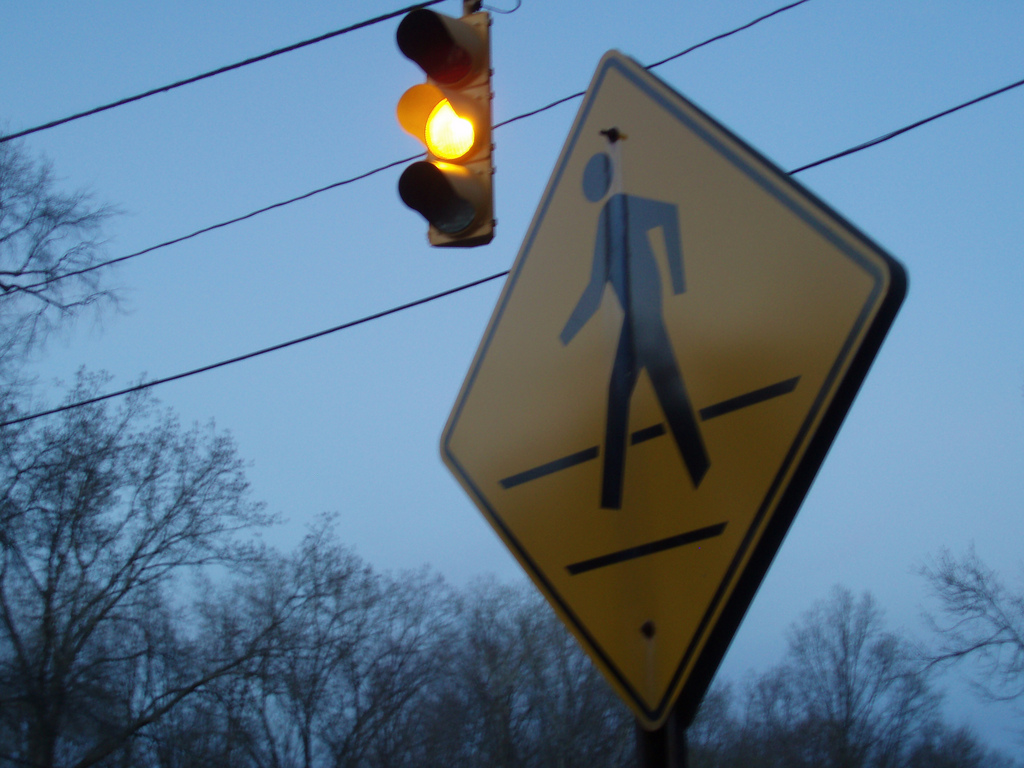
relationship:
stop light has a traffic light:
[393, 1, 495, 248] [392, 80, 493, 166]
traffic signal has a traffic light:
[393, 1, 495, 248] [392, 80, 493, 166]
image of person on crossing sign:
[559, 154, 716, 503] [438, 46, 907, 729]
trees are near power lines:
[4, 140, 1021, 767] [1, 0, 1023, 432]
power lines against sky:
[1, 0, 1023, 432] [1, 0, 1021, 768]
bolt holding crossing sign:
[594, 123, 617, 144] [438, 46, 907, 729]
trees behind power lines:
[4, 140, 1021, 767] [1, 0, 1023, 432]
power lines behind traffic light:
[1, 0, 1023, 432] [396, 84, 485, 160]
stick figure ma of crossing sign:
[559, 154, 716, 503] [438, 46, 907, 729]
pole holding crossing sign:
[632, 709, 683, 766] [438, 46, 907, 729]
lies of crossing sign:
[499, 376, 800, 576] [438, 46, 907, 729]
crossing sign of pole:
[438, 46, 907, 729] [632, 709, 683, 766]